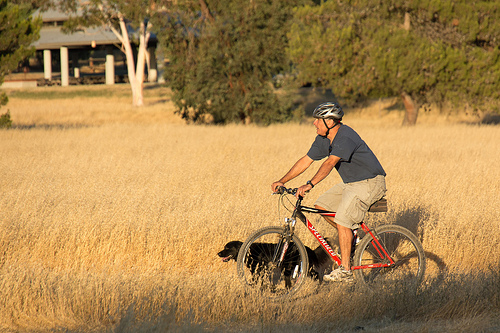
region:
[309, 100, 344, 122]
silver and black bike helmet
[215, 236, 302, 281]
black dog is panting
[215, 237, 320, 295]
black lab walking next to bike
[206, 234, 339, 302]
black dog in field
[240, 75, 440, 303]
man riding red bike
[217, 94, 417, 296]
man riding red bike in field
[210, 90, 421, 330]
man riding red bike next to dog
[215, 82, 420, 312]
man riding red bike next to black dog in field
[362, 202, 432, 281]
shadow of man on bike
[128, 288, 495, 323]
shadow in field grass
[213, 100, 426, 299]
Man riding a bike with his dog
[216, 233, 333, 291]
Medium sized black dog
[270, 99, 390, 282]
Man wearing a slate blue shirt and khaki shorts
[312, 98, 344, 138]
Silver and black helmet on a mans head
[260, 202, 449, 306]
Shadow of a man riding his bike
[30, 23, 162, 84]
Medium sized picnic pavilion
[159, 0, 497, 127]
Dense group of green trees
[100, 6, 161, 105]
White tree trunk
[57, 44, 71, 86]
Concrete pavilion support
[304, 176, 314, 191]
Watch on a wrist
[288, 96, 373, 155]
man wearing a helmet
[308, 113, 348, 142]
helmet has black straps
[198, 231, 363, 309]
dog walking beside man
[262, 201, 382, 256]
the bike is red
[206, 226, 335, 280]
the dog is black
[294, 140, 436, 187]
man's shirt is gray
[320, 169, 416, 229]
man's shorts are brown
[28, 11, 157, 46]
the roof is gray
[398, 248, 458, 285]
shadow of bike wheel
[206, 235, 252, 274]
dog's tongue is out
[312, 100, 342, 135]
a gray and black helmet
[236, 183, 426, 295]
a red and black bike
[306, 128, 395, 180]
a man's blue shirt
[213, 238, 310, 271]
a black dog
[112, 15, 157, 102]
a tall gray tree branch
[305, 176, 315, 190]
a man's black wristwatch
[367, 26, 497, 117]
part of a green tree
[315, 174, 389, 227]
a man's brown shorts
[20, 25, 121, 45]
the roof of a building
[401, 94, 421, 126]
part of a tree branch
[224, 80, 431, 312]
a man riding a bike.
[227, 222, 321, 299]
a front bike tire.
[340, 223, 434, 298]
a rear back tire.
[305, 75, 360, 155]
a man wearing a helmet.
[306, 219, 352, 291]
a left human leg.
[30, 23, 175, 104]
a structure with a roof.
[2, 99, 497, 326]
a field of tall yellow grass.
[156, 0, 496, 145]
a forest of green trees.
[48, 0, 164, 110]
a tree with green leaves.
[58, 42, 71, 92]
a tall cement pillar.